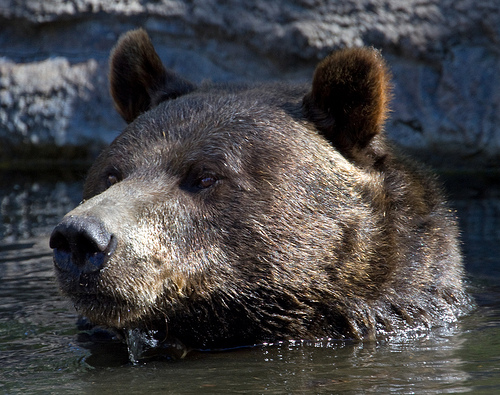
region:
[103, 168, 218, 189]
The eyes of the bear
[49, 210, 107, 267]
The nose of the bear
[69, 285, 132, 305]
The mouth of the bear is closed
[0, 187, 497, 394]
Water around the bear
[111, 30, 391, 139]
The ears of the bear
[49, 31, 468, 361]
A bear in the water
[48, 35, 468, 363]
The bear is brown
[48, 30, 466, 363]
The bear has wet fur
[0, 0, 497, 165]
A stone wall behind the bear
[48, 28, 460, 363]
The head of the bear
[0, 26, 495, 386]
a brown bear swimming in water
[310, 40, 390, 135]
a brown bear's ear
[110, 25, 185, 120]
ear of a brown bear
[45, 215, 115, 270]
black nose of a bear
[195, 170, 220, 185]
left eye of the bear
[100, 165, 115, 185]
right eye of the bear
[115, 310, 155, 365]
water dripping off the bear's chin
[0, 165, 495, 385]
water occupied by a large bear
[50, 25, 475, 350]
the bear's fur is brown and wet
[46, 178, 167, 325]
snout of the brown bear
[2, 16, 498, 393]
The bear is in the water.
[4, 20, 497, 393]
Bear's head is sticking out of the water.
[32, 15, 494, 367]
The bear's haed is furry.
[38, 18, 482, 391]
The bear has a black nose.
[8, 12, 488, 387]
The bear has two ears.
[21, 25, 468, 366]
The bear has two eyes.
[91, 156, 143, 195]
The eye is open.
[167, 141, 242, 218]
The eye is open.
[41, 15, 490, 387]
The bear is alert.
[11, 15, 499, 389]
The bear is cooling off.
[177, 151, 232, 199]
Left eye of a grizzly bear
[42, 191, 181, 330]
Snout and mouth of a grizzly bear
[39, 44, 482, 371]
Grizzly bear swimming in a river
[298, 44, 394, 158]
Left ear of a brown grizzle bear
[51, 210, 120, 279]
Black nose of a brown grizzly bear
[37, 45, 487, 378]
Head of a brown grizzly bear popping out of water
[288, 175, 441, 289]
Patch of brown grizzly bear fur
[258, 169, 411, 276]
Patch of fur from a brown bear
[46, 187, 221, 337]
Snout and mouth of a brown bear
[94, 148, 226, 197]
Eyes of a brown grizzly bear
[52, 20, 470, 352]
the head of a brown bear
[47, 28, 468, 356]
a bear in water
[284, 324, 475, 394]
the bear's reflection in the water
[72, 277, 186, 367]
water dripping down the bear's face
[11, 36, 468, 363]
water surrounding a bear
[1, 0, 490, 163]
a rock wall behind the bear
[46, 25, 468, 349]
a bear in front of a rock wall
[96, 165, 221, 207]
the bear has brown eyes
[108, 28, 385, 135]
the bear has two ears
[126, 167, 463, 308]
the sun is reflecting off of the bear